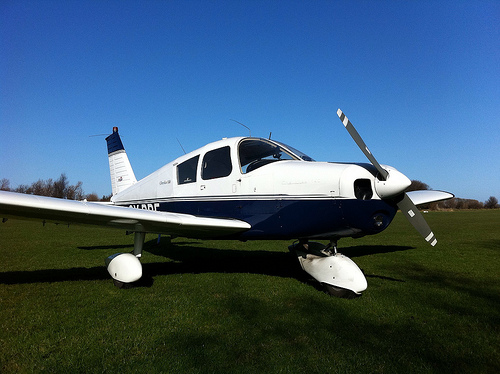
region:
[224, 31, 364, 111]
this is the sky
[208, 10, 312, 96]
the sky is blue in color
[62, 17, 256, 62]
the sky is clear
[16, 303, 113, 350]
this is the grass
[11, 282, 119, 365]
the grass is green in color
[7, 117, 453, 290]
this is an airplane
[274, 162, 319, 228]
the airplane is white and blue in color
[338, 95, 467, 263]
this is the propeller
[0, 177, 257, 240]
this is a wing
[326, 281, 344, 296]
this is a wheel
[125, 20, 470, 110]
this is the sky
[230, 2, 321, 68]
thew sky is blue in color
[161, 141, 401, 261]
this is a jet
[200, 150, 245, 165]
this is a window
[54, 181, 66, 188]
the tree has green aeves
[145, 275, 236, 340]
this is a ground area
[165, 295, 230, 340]
the grass is green in color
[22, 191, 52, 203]
the wing is white in color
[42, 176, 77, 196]
this is a tree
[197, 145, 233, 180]
the window of the plane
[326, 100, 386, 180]
a black and white propeller blade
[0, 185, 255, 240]
the wing of a plane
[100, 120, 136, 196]
the tail of a plane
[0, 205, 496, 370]
a grassy green field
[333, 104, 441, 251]
the propellers of a plane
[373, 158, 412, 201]
the nose of a plane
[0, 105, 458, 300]
a white and black plane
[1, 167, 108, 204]
a row of trees behind the plane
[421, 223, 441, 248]
white stripes on the propeller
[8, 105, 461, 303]
Blue and white airplane parked on grass.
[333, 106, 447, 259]
Propeller on front of airplane.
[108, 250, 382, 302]
White covers on wheels.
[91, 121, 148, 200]
White and blue rear tail.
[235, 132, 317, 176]
Front window covering cockpit.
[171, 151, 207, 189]
A side passenger window.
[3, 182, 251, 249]
White wing on airplane.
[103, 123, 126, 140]
Tail light on airplane.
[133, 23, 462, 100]
A clear blue sky above airplane.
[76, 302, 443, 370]
Green grass airplane is parked on.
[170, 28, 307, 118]
this is the sky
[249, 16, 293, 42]
the sky is blue in color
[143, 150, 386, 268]
this is a jet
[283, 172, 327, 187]
the jet is white in color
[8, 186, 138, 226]
this is a wing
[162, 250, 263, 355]
this is a grass area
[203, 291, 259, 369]
the grass is green in color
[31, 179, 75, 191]
this is a tree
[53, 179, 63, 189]
the tree has green leaves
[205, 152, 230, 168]
this is a window